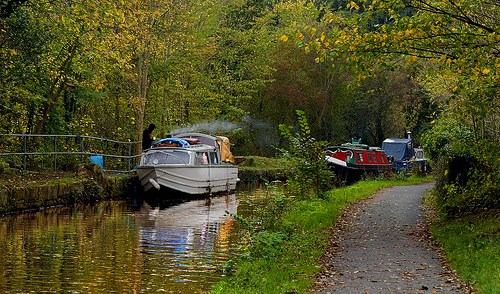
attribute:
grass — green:
[419, 178, 497, 271]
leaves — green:
[173, 34, 278, 77]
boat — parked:
[323, 140, 418, 185]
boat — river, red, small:
[319, 140, 389, 172]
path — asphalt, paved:
[368, 206, 436, 259]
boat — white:
[137, 132, 240, 201]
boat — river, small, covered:
[123, 119, 272, 216]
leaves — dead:
[410, 209, 469, 281]